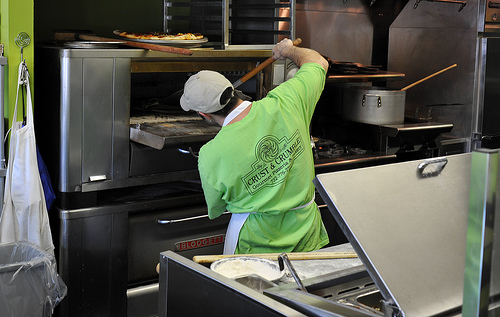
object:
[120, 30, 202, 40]
pizza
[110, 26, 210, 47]
pan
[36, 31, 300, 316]
oven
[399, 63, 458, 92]
spoon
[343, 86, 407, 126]
pot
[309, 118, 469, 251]
stove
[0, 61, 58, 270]
apron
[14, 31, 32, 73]
hook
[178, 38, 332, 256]
man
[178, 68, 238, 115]
baseball cap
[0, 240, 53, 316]
trash can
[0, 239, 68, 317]
liner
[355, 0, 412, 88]
chimney vent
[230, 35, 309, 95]
paddle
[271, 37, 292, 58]
hand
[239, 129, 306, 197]
logo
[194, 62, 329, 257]
shirt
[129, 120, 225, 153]
door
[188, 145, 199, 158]
handle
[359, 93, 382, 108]
handle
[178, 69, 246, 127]
head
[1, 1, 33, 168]
wall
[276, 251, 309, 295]
ladle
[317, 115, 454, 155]
shelf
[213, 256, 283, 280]
flour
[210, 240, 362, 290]
table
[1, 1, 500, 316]
kitchen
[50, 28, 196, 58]
paddle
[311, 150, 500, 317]
lid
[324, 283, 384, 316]
container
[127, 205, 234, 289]
door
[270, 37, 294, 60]
glove